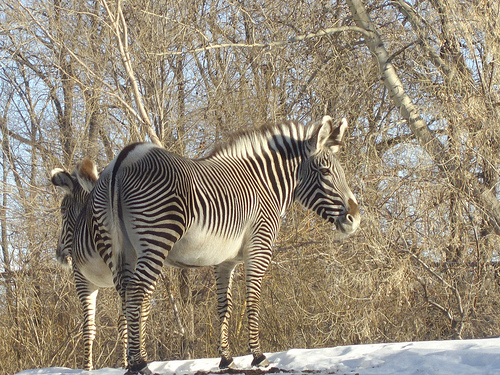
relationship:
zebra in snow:
[98, 134, 342, 280] [237, 352, 376, 372]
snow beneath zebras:
[300, 345, 426, 366] [29, 146, 376, 331]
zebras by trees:
[50, 154, 122, 369] [294, 54, 454, 240]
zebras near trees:
[33, 154, 318, 348] [337, 57, 467, 197]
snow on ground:
[350, 346, 431, 362] [177, 355, 210, 373]